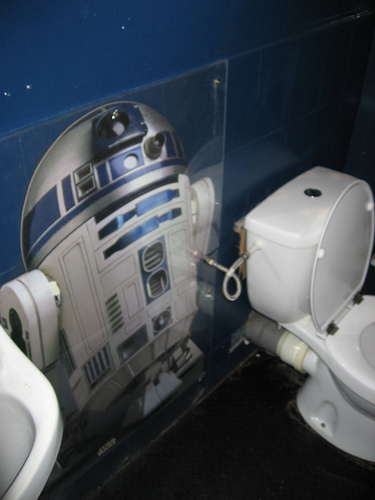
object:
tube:
[210, 247, 249, 303]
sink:
[0, 317, 64, 500]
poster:
[1, 57, 231, 469]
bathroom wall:
[0, 1, 374, 499]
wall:
[0, 4, 319, 499]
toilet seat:
[323, 296, 374, 389]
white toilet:
[242, 165, 374, 463]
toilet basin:
[242, 164, 357, 326]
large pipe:
[242, 315, 314, 375]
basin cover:
[241, 164, 364, 251]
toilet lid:
[310, 179, 373, 331]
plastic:
[0, 2, 252, 469]